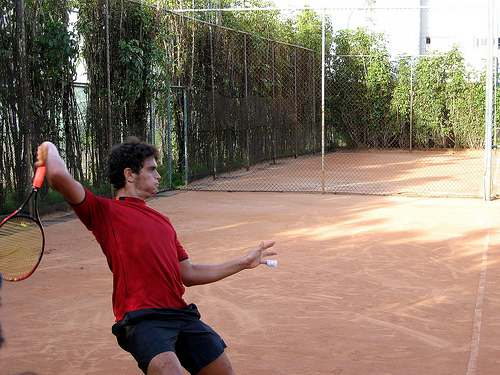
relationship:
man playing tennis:
[34, 122, 266, 369] [13, 124, 48, 251]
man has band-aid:
[34, 122, 266, 369] [264, 259, 276, 269]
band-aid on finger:
[264, 259, 276, 269] [263, 259, 266, 265]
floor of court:
[338, 240, 396, 258] [224, 201, 345, 231]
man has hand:
[34, 122, 266, 369] [243, 235, 279, 276]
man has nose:
[34, 122, 266, 369] [152, 172, 162, 178]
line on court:
[469, 267, 493, 317] [224, 201, 345, 231]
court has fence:
[224, 201, 345, 231] [203, 53, 318, 118]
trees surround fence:
[81, 27, 156, 118] [203, 53, 318, 118]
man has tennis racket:
[34, 122, 266, 369] [1, 172, 50, 289]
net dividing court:
[218, 84, 437, 157] [224, 201, 345, 231]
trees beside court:
[81, 27, 156, 118] [224, 201, 345, 231]